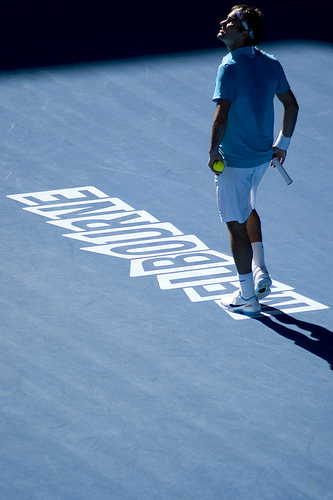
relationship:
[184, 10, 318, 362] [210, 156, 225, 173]
man has ball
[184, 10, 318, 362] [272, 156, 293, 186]
man holds racket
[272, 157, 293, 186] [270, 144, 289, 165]
handle on hand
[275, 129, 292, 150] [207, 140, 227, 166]
band on wrist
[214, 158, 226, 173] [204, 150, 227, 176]
ball in hand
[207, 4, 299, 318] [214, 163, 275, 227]
man wearing shorts.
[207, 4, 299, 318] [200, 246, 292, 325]
man wearing shoes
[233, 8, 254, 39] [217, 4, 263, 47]
headband on head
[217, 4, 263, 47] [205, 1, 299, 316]
head of man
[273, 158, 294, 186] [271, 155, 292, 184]
grip of racquet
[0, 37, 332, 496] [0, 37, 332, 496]
tarp on tarp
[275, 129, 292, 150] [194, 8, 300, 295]
band on man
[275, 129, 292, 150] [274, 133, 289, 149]
band on wrist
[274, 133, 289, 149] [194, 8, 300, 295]
wrist of man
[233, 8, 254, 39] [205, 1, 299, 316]
headband on man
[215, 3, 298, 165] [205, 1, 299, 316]
shirt on man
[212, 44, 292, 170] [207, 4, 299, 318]
shirt on man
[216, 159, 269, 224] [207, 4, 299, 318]
shorts on man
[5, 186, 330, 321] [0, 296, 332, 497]
letters on floor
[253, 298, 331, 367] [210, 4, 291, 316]
shadow of man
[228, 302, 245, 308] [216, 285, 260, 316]
swoosh on shoe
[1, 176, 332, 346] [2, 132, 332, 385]
letters on floor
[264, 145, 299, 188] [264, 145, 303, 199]
handle of racket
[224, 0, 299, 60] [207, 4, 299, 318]
headband of man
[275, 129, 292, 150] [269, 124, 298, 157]
band on wrist